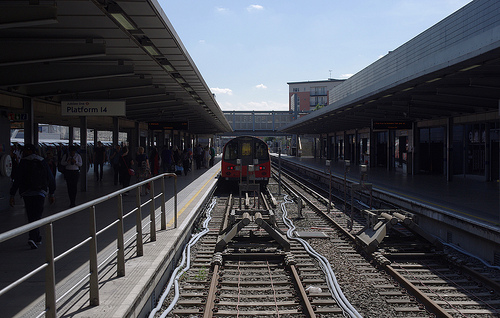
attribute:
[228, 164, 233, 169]
light — red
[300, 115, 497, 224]
walkway — empty